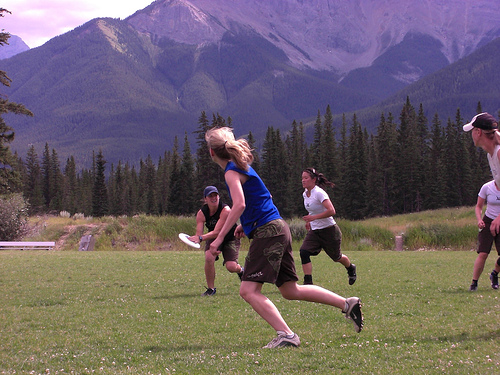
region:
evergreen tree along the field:
[141, 160, 159, 217]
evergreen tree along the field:
[92, 149, 117, 216]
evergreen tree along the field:
[37, 140, 57, 215]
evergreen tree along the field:
[341, 115, 375, 223]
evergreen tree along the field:
[377, 118, 421, 220]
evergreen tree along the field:
[71, 162, 84, 217]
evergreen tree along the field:
[26, 143, 45, 207]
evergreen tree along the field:
[51, 145, 69, 208]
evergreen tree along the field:
[111, 160, 133, 212]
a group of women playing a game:
[173, 98, 498, 371]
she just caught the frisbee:
[168, 180, 253, 292]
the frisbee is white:
[166, 220, 219, 257]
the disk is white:
[168, 225, 218, 268]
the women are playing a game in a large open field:
[104, 95, 495, 361]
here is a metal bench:
[0, 225, 76, 263]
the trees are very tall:
[28, 84, 493, 247]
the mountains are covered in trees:
[3, 3, 498, 210]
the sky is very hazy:
[3, 5, 145, 54]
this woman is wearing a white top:
[287, 160, 386, 290]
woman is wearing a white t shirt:
[300, 168, 358, 287]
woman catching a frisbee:
[176, 185, 251, 297]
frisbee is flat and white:
[178, 231, 200, 251]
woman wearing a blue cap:
[203, 185, 219, 196]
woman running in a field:
[206, 126, 366, 353]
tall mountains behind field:
[0, 1, 499, 176]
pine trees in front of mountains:
[2, 93, 498, 222]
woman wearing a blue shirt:
[223, 161, 283, 238]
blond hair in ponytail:
[206, 125, 252, 172]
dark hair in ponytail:
[301, 167, 336, 194]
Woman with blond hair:
[202, 125, 254, 169]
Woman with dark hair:
[298, 163, 338, 195]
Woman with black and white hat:
[462, 110, 498, 147]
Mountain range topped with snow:
[128, 0, 485, 60]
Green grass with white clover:
[37, 333, 207, 366]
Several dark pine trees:
[23, 143, 178, 215]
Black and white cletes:
[345, 293, 367, 334]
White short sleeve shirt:
[302, 185, 340, 230]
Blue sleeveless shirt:
[223, 158, 282, 237]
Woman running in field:
[297, 168, 360, 288]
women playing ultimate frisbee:
[121, 94, 483, 374]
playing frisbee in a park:
[142, 108, 489, 373]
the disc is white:
[177, 233, 208, 260]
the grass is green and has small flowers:
[55, 315, 225, 365]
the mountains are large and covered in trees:
[90, 0, 436, 155]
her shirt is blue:
[210, 157, 280, 233]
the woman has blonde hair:
[185, 115, 381, 370]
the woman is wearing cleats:
[157, 98, 398, 371]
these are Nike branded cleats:
[251, 297, 416, 357]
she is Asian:
[294, 156, 369, 298]